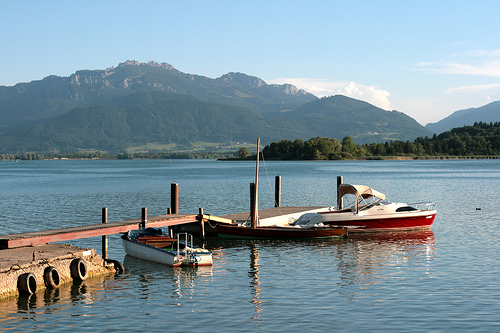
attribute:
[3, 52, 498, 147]
mountain — Large 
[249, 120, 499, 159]
trees — green , dark , thick 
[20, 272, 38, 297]
tire — black, small 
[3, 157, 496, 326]
water — calm 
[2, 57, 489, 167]
mountains — distance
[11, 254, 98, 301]
black tires — bumpers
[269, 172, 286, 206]
dock beam — brown wooden doc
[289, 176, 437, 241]
boat — white , orange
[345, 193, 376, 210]
railings — Metal 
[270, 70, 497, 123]
cloud — white 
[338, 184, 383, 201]
covering — White 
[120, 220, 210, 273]
boat — docked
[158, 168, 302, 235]
posts — four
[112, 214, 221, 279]
boat — white